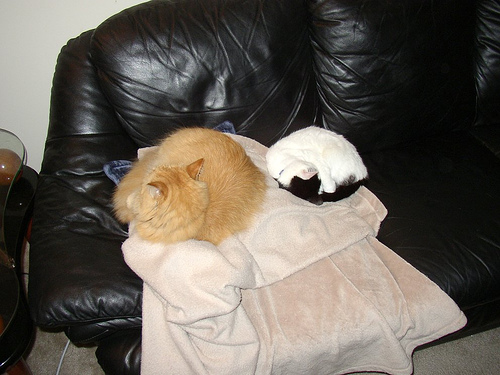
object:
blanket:
[120, 132, 467, 374]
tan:
[210, 158, 245, 194]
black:
[300, 185, 314, 199]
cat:
[264, 125, 370, 203]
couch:
[28, 2, 497, 375]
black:
[126, 40, 180, 67]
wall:
[0, 0, 150, 170]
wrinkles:
[316, 70, 338, 113]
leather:
[367, 43, 423, 99]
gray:
[438, 348, 480, 366]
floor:
[407, 338, 499, 375]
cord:
[50, 342, 68, 375]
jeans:
[104, 159, 132, 185]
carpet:
[25, 330, 92, 374]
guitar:
[1, 126, 28, 375]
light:
[129, 57, 155, 78]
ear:
[186, 158, 206, 181]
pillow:
[122, 130, 382, 322]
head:
[127, 158, 208, 228]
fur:
[216, 155, 233, 175]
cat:
[111, 126, 267, 244]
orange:
[216, 166, 240, 195]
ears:
[147, 181, 168, 198]